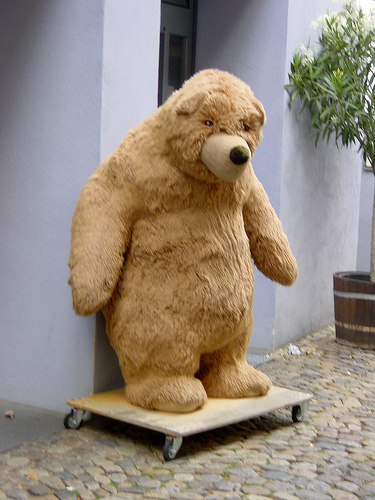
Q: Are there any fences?
A: No, there are no fences.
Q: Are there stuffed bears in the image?
A: Yes, there is a stuffed bear.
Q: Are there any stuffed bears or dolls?
A: Yes, there is a stuffed bear.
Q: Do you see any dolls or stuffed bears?
A: Yes, there is a stuffed bear.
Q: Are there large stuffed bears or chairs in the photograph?
A: Yes, there is a large stuffed bear.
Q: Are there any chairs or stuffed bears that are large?
A: Yes, the stuffed bear is large.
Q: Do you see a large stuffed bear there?
A: Yes, there is a large stuffed bear.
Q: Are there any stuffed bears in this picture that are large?
A: Yes, there is a stuffed bear that is large.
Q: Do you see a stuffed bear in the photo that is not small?
A: Yes, there is a large stuffed bear.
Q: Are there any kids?
A: No, there are no kids.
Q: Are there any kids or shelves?
A: No, there are no kids or shelves.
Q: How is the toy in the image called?
A: The toy is a stuffed bear.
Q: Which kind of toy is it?
A: The toy is a stuffed bear.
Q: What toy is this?
A: This is a stuffed bear.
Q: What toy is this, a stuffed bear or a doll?
A: This is a stuffed bear.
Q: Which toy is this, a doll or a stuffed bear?
A: This is a stuffed bear.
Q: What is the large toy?
A: The toy is a stuffed bear.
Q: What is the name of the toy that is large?
A: The toy is a stuffed bear.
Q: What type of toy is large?
A: The toy is a stuffed bear.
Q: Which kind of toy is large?
A: The toy is a stuffed bear.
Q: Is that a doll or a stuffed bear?
A: That is a stuffed bear.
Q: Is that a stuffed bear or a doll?
A: That is a stuffed bear.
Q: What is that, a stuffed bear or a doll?
A: That is a stuffed bear.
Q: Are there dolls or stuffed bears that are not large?
A: No, there is a stuffed bear but it is large.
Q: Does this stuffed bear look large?
A: Yes, the stuffed bear is large.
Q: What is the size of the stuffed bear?
A: The stuffed bear is large.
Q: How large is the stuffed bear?
A: The stuffed bear is large.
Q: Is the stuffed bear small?
A: No, the stuffed bear is large.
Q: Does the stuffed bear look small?
A: No, the stuffed bear is large.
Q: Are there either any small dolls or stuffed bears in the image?
A: No, there is a stuffed bear but it is large.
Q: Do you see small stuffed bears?
A: No, there is a stuffed bear but it is large.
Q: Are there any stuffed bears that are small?
A: No, there is a stuffed bear but it is large.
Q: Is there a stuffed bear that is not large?
A: No, there is a stuffed bear but it is large.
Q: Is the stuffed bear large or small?
A: The stuffed bear is large.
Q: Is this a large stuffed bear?
A: Yes, this is a large stuffed bear.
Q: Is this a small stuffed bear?
A: No, this is a large stuffed bear.